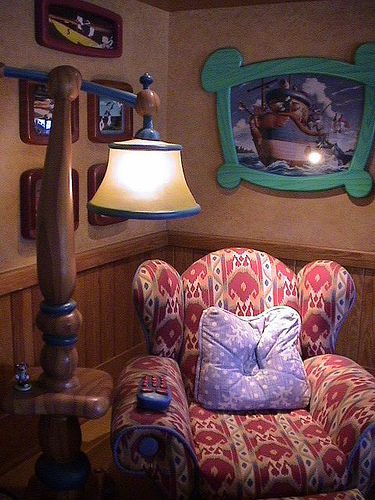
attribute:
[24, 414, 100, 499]
base — wooden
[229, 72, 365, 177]
picture — green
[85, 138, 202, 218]
lamp shade — white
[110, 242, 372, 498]
chair — comfy, comfortable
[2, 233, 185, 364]
paneling — wooden